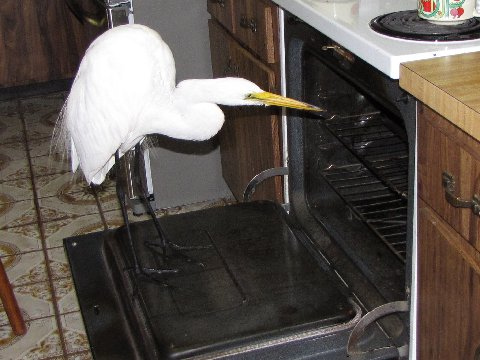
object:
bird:
[50, 24, 324, 289]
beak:
[251, 91, 323, 112]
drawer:
[205, 0, 274, 60]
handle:
[238, 18, 256, 32]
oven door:
[59, 196, 395, 357]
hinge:
[348, 300, 411, 360]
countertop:
[397, 51, 480, 143]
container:
[419, 0, 479, 28]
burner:
[370, 6, 480, 39]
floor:
[1, 86, 236, 359]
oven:
[286, 19, 416, 351]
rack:
[323, 109, 410, 203]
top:
[273, 1, 478, 81]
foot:
[150, 238, 209, 267]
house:
[1, 2, 478, 360]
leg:
[135, 142, 167, 244]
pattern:
[5, 163, 70, 192]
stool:
[0, 257, 26, 336]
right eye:
[245, 93, 253, 100]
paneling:
[2, 0, 111, 87]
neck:
[170, 79, 225, 140]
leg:
[116, 149, 140, 272]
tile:
[38, 191, 100, 221]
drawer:
[413, 107, 479, 254]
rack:
[322, 156, 408, 265]